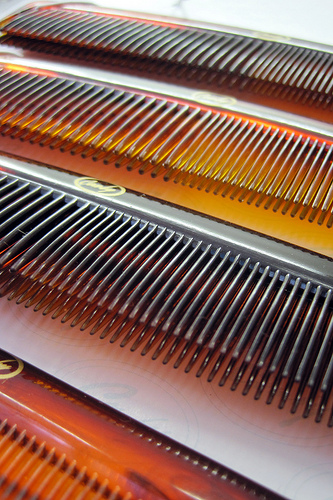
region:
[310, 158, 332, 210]
small silver metal piece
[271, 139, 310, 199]
small silver metal piece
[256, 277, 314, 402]
small silver metal piece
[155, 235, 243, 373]
small silver metal piece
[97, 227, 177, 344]
small silver metal piece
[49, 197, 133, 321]
small silver metal piece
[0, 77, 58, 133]
small silver metal piece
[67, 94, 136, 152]
small silver metal piece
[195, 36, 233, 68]
small silver metal piece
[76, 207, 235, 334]
the fine brown comb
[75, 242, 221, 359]
the fine brown comb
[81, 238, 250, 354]
the fine brown comb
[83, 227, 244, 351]
the fine brown comb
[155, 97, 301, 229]
the combs are fine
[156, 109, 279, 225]
the combs are fine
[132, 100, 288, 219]
the combs are fine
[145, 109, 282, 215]
the combs are fine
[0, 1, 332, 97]
Dark brown comb.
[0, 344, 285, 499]
Light brown comb.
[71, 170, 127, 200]
Logo on the comb.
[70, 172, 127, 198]
Gold color on the comb.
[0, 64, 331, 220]
Teeth on the comb.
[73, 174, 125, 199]
Letters on the comb.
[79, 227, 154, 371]
the bristles of a dark brown comb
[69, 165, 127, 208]
the logo of a dark brown comb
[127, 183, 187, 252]
the non bristle side of a dark brown comb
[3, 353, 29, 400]
the logo of a light brown comb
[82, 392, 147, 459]
the non bristles of a light brown comb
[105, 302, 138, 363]
the point of a combs bristle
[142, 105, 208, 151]
the plastic part of a comb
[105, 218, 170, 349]
A tine on a comb.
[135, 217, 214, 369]
A tine on a comb.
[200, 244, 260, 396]
A tine on a comb.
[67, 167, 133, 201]
stylized yellow emblem on polished edge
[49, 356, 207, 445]
fancy decorative embossed black logo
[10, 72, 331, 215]
row of reflective metal keys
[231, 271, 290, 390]
tooth belongs to comb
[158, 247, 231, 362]
tooth belongs to comb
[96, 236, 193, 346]
tooth belongs to comb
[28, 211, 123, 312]
tooth belongs to comb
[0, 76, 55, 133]
tooth belongs to comb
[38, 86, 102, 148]
tooth belongs to comb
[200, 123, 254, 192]
tooth belongs to comb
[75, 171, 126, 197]
a white circle with white words inside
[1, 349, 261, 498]
a translucent orange colored comb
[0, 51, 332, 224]
a silver, yellow, and orange comb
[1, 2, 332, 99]
silver, red, and black comb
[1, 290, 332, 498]
white paper with gray circles on it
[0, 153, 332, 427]
two combs that are identical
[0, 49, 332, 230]
two combs on top of yellow paper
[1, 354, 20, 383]
a yellow circle with yellow writing inside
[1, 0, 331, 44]
a blurred background